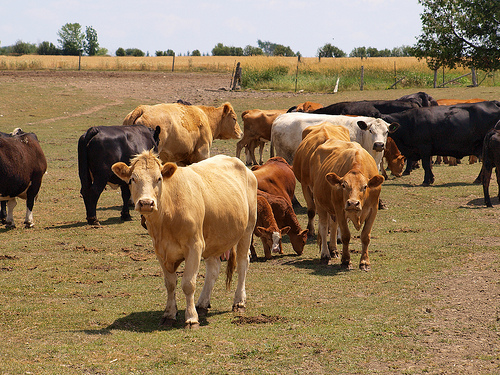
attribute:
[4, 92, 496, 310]
cows — colorful, black,   together,  a large group, large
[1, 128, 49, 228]
cow — brown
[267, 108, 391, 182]
cow — white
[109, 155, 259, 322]
cow — tan, forward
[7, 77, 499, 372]
grass — green, brown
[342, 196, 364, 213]
snout — brown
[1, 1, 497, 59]
sky — blue